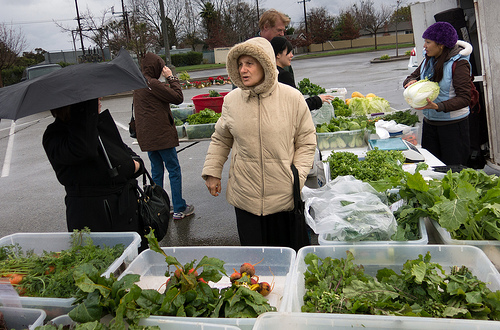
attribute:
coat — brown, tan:
[198, 31, 318, 216]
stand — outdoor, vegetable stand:
[5, 235, 497, 318]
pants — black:
[235, 212, 292, 239]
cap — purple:
[418, 22, 463, 48]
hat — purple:
[424, 19, 459, 55]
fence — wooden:
[305, 31, 414, 54]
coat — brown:
[131, 50, 184, 150]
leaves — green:
[325, 259, 499, 314]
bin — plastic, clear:
[238, 233, 483, 324]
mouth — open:
[237, 75, 253, 82]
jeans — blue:
[162, 179, 354, 239]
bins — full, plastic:
[6, 237, 446, 317]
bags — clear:
[307, 165, 399, 247]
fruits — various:
[1, 88, 498, 328]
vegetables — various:
[3, 97, 499, 329]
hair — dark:
[431, 42, 460, 80]